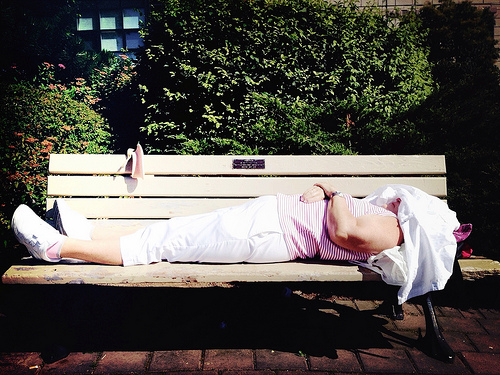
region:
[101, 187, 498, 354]
A person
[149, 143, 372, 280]
A person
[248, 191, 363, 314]
A person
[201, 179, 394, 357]
A person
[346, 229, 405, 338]
A person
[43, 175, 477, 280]
tired woman on a bench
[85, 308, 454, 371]
brick tiling under the bench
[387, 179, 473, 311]
coat of the woman on the bench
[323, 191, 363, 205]
watch of the woman on the bench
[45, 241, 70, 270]
pink socks of the lady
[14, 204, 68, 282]
white tennis shoes on the lady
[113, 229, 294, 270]
white capris of the woman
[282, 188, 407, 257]
pink stripped shirt of the lady on the bench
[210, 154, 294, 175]
dedication of who donated the bench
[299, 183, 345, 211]
hands of the sleeping woman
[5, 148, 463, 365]
a wooden park bench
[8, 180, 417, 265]
a woman resting on a park bench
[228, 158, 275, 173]
a plaque on a park bench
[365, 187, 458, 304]
a white cloth is covering the woman's head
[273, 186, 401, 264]
the woman is wearing a shirt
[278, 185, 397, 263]
the shirt is pink and white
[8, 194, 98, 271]
the tennis shoes are white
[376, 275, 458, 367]
iron legs on the park bench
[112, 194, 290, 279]
the woman's pants are white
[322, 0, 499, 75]
a tan wall in the background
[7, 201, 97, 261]
The lady's white sneakers.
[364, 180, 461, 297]
The white jacket over the lady's head.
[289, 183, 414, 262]
The striped t-shirt the lady is wearing.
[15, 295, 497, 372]
The brick sidewalk the bench is located on.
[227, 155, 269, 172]
The small black plaque that is on the bench.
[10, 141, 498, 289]
The wooden bench the lady is laying on.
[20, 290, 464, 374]
The black wrought iron legs of the bench.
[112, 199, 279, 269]
The white capri shorts the lady is wearing.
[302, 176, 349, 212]
The lady's hands on her stomach.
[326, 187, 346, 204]
The silver watch on the lady's wrist.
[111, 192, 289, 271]
Woman wears white pants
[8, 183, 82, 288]
Woman wears white sneakers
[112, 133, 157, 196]
Pink and white towel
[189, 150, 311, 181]
Small plaque on bench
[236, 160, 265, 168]
White lettering on plaque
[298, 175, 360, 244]
Woman's arms are folded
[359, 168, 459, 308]
White shirt on woman's face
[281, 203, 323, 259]
Woman is wearing pink and white shirt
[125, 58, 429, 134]
Big green bushes behind bench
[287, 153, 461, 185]
Beige bench woman is on